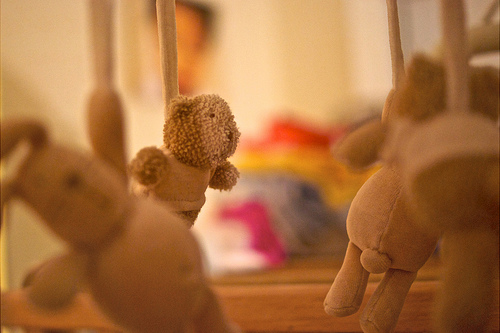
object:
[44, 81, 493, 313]
toys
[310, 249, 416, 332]
legs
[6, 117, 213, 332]
bear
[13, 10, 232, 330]
bears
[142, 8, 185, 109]
stick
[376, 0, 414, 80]
stick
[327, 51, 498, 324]
bears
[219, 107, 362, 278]
clothes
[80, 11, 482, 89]
straps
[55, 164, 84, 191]
nose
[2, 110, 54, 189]
ears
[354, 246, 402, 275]
tail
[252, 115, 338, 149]
clothing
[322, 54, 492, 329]
animal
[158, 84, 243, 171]
head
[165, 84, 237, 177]
texture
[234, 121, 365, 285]
bed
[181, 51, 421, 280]
distance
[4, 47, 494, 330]
animals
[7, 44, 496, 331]
air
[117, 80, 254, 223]
animal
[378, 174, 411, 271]
seam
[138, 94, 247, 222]
bear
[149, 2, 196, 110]
pole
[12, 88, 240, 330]
bunny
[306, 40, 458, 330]
bunny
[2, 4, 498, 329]
photo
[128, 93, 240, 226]
teddy bear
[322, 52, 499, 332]
teddy bear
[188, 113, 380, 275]
object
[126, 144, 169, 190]
arm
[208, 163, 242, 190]
arm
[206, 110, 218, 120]
eye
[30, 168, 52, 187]
eye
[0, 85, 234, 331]
teddy bear